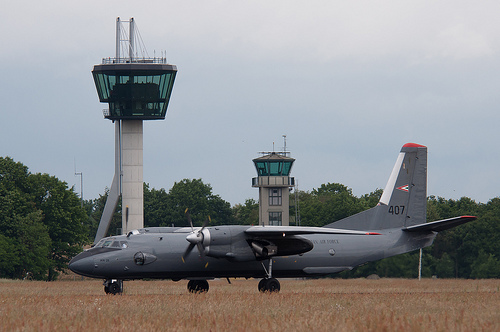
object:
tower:
[246, 133, 304, 233]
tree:
[195, 178, 217, 193]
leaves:
[1, 147, 498, 295]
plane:
[93, 230, 389, 277]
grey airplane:
[72, 143, 479, 308]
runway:
[4, 277, 499, 330]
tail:
[373, 142, 483, 254]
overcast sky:
[0, 0, 498, 200]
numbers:
[381, 199, 411, 219]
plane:
[64, 138, 477, 299]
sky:
[3, 3, 497, 206]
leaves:
[12, 197, 102, 268]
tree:
[2, 154, 89, 288]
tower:
[101, 100, 146, 231]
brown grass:
[2, 275, 499, 329]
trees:
[2, 158, 109, 281]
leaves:
[45, 226, 56, 236]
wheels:
[104, 278, 294, 295]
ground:
[63, 294, 468, 329]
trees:
[13, 153, 89, 248]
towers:
[97, 38, 179, 208]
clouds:
[195, 4, 496, 80]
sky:
[3, 2, 495, 143]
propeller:
[181, 219, 226, 273]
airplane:
[66, 140, 482, 294]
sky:
[23, 5, 498, 230]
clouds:
[311, 37, 493, 149]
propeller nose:
[179, 230, 201, 247]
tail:
[370, 136, 460, 244]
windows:
[93, 74, 170, 114]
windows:
[266, 154, 281, 174]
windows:
[282, 157, 291, 177]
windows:
[250, 155, 266, 178]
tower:
[244, 141, 303, 227]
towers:
[70, 34, 388, 223]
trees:
[4, 155, 65, 280]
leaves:
[1, 155, 94, 280]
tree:
[0, 154, 95, 280]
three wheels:
[100, 276, 289, 297]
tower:
[88, 15, 177, 245]